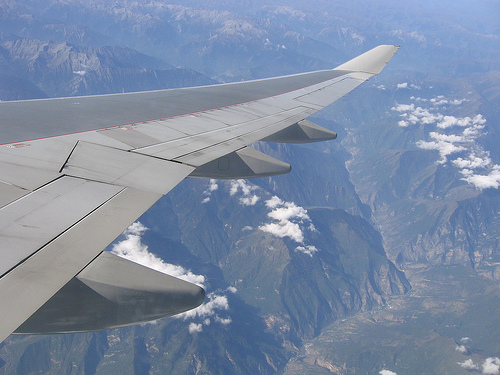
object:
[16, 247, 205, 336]
propellers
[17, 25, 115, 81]
sun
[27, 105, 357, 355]
tanks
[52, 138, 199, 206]
spoiler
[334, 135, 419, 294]
chasm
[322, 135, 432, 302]
river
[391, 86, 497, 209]
formation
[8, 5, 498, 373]
chain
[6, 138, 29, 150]
light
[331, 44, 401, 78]
tip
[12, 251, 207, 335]
bottom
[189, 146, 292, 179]
bottom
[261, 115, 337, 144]
bottom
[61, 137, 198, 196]
flap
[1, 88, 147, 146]
front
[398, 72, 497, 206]
clouds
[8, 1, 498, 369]
sky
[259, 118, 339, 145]
engine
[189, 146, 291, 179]
engine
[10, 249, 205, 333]
engine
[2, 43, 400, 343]
airplane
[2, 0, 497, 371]
mountain top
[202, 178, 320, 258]
snow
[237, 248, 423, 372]
valley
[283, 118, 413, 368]
creek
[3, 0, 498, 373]
landcape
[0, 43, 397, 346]
wings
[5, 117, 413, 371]
hills